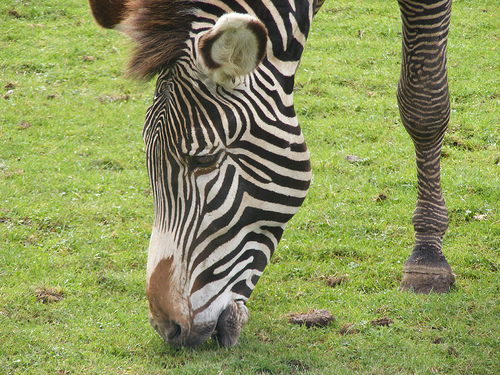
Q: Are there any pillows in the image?
A: No, there are no pillows.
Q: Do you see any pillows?
A: No, there are no pillows.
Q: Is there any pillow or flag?
A: No, there are no pillows or flags.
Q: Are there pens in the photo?
A: No, there are no pens.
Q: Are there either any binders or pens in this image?
A: No, there are no pens or binders.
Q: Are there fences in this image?
A: No, there are no fences.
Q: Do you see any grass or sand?
A: Yes, there is grass.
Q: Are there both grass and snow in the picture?
A: No, there is grass but no snow.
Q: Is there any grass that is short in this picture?
A: Yes, there is short grass.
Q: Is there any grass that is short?
A: Yes, there is grass that is short.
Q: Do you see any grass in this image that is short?
A: Yes, there is grass that is short.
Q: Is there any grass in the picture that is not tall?
A: Yes, there is short grass.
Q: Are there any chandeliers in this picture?
A: No, there are no chandeliers.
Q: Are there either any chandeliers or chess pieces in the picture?
A: No, there are no chandeliers or chess pieces.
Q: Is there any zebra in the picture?
A: Yes, there is a zebra.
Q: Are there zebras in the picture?
A: Yes, there is a zebra.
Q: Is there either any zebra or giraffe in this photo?
A: Yes, there is a zebra.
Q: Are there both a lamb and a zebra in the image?
A: No, there is a zebra but no lambs.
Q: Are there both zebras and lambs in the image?
A: No, there is a zebra but no lambs.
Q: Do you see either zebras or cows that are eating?
A: Yes, the zebra is eating.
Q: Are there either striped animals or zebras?
A: Yes, there is a striped zebra.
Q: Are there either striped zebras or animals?
A: Yes, there is a striped zebra.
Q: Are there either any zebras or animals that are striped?
A: Yes, the zebra is striped.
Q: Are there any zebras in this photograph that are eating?
A: Yes, there is a zebra that is eating.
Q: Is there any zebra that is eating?
A: Yes, there is a zebra that is eating.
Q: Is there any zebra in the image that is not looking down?
A: Yes, there is a zebra that is eating.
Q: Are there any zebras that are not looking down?
A: Yes, there is a zebra that is eating.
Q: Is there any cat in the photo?
A: No, there are no cats.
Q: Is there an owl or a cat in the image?
A: No, there are no cats or owls.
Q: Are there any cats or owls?
A: No, there are no cats or owls.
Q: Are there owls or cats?
A: No, there are no cats or owls.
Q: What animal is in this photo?
A: The animal is a zebra.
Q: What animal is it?
A: The animal is a zebra.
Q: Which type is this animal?
A: This is a zebra.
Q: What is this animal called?
A: This is a zebra.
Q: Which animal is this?
A: This is a zebra.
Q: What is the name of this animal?
A: This is a zebra.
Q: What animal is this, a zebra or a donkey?
A: This is a zebra.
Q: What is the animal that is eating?
A: The animal is a zebra.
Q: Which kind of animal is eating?
A: The animal is a zebra.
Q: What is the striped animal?
A: The animal is a zebra.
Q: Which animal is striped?
A: The animal is a zebra.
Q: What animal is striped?
A: The animal is a zebra.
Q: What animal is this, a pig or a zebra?
A: This is a zebra.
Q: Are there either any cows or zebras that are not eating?
A: No, there is a zebra but it is eating.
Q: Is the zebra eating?
A: Yes, the zebra is eating.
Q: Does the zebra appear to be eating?
A: Yes, the zebra is eating.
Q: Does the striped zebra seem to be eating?
A: Yes, the zebra is eating.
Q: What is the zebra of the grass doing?
A: The zebra is eating.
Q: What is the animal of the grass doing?
A: The zebra is eating.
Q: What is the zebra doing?
A: The zebra is eating.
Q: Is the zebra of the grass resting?
A: No, the zebra is eating.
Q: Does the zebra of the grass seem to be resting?
A: No, the zebra is eating.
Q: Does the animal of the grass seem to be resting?
A: No, the zebra is eating.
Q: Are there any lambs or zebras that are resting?
A: No, there is a zebra but it is eating.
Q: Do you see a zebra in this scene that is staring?
A: No, there is a zebra but it is eating.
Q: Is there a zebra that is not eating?
A: No, there is a zebra but it is eating.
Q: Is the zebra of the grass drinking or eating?
A: The zebra is eating.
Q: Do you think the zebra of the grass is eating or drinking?
A: The zebra is eating.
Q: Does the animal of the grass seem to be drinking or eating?
A: The zebra is eating.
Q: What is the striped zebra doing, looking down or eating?
A: The zebra is eating.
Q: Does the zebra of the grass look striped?
A: Yes, the zebra is striped.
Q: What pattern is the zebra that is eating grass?
A: The zebra is striped.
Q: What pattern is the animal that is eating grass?
A: The zebra is striped.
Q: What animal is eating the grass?
A: The zebra is eating the grass.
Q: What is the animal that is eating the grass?
A: The animal is a zebra.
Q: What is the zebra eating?
A: The zebra is eating grass.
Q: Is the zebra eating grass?
A: Yes, the zebra is eating grass.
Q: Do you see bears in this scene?
A: No, there are no bears.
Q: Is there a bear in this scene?
A: No, there are no bears.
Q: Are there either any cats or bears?
A: No, there are no bears or cats.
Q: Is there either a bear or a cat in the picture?
A: No, there are no bears or cats.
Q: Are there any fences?
A: No, there are no fences.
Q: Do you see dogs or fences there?
A: No, there are no fences or dogs.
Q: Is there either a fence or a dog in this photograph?
A: No, there are no fences or dogs.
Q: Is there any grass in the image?
A: Yes, there is grass.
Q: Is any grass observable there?
A: Yes, there is grass.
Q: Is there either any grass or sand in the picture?
A: Yes, there is grass.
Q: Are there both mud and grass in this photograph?
A: No, there is grass but no mud.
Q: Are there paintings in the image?
A: No, there are no paintings.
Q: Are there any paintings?
A: No, there are no paintings.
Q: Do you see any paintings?
A: No, there are no paintings.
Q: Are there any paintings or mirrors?
A: No, there are no paintings or mirrors.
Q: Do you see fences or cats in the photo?
A: No, there are no fences or cats.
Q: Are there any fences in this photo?
A: No, there are no fences.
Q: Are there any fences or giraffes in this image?
A: No, there are no fences or giraffes.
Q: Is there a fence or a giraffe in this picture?
A: No, there are no fences or giraffes.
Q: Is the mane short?
A: Yes, the mane is short.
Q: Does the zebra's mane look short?
A: Yes, the mane is short.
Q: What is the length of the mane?
A: The mane is short.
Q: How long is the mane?
A: The mane is short.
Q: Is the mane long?
A: No, the mane is short.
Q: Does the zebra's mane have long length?
A: No, the mane is short.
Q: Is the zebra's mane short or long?
A: The mane is short.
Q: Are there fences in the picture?
A: No, there are no fences.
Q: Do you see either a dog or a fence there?
A: No, there are no fences or dogs.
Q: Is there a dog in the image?
A: No, there are no dogs.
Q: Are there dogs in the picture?
A: No, there are no dogs.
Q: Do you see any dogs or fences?
A: No, there are no dogs or fences.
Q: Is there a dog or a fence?
A: No, there are no dogs or fences.